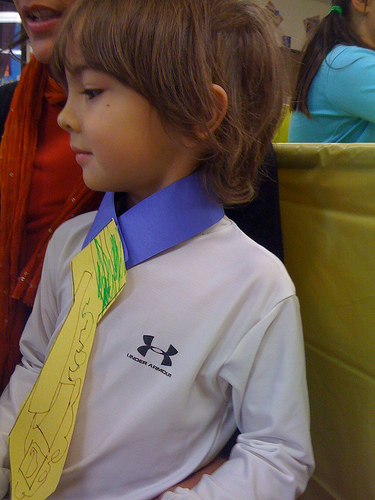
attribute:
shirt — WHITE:
[4, 178, 336, 483]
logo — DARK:
[127, 328, 183, 385]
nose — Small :
[53, 83, 81, 132]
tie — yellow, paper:
[7, 169, 223, 499]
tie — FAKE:
[45, 204, 118, 350]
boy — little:
[1, 10, 327, 497]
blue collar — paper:
[80, 164, 225, 267]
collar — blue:
[81, 190, 225, 268]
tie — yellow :
[6, 217, 128, 498]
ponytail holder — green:
[327, 4, 340, 15]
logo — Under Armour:
[123, 330, 181, 384]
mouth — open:
[22, 3, 65, 27]